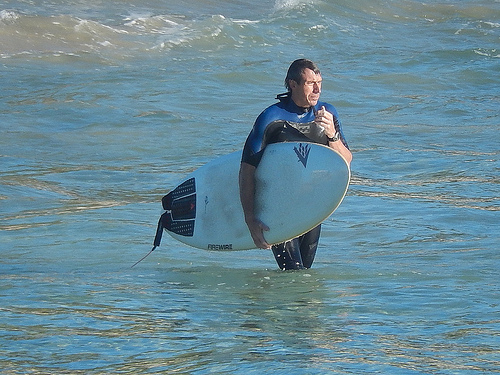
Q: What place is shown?
A: It is a sea.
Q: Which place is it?
A: It is a sea.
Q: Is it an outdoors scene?
A: Yes, it is outdoors.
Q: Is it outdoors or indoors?
A: It is outdoors.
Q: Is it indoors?
A: No, it is outdoors.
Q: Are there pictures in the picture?
A: No, there are no pictures.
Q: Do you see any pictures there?
A: No, there are no pictures.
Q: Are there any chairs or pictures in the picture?
A: No, there are no pictures or chairs.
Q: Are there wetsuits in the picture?
A: Yes, there is a wetsuit.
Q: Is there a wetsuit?
A: Yes, there is a wetsuit.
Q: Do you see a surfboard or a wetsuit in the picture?
A: Yes, there is a wetsuit.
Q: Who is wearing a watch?
A: The man is wearing a watch.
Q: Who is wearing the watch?
A: The man is wearing a watch.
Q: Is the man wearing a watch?
A: Yes, the man is wearing a watch.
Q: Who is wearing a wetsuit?
A: The man is wearing a wetsuit.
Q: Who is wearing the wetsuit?
A: The man is wearing a wetsuit.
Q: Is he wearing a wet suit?
A: Yes, the man is wearing a wet suit.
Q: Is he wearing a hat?
A: No, the man is wearing a wet suit.